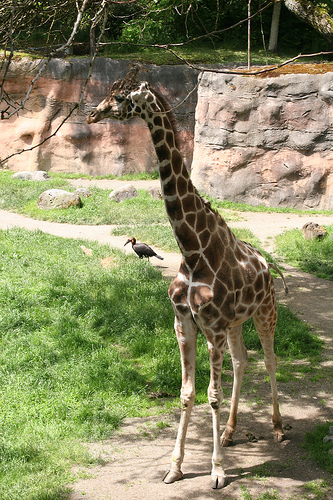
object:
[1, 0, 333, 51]
forest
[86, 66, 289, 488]
giraffe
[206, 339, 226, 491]
leg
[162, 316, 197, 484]
leg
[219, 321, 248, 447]
leg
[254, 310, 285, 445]
leg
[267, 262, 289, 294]
tail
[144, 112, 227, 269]
neck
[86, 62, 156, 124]
head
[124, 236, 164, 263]
bird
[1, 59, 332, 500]
pen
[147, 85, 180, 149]
mane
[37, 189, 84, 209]
rock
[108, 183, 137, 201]
rock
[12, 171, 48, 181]
rock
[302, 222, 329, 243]
rock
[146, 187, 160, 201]
rock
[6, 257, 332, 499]
shadow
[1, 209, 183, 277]
path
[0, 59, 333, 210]
wall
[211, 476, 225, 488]
hoof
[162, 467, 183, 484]
hoof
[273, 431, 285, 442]
hoof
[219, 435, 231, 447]
hoof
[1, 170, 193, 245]
grass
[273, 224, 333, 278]
grass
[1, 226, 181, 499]
grass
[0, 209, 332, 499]
path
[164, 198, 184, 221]
spot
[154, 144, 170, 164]
spot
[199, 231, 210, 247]
spot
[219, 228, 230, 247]
spot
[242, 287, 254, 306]
spot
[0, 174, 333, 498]
ground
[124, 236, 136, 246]
head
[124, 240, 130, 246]
beak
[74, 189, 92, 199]
rock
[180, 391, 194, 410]
knee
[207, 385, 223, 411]
knee